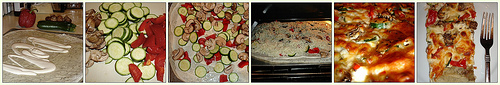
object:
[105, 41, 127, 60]
zuchinni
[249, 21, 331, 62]
pepper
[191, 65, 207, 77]
veggies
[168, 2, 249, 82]
sauce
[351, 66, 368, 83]
cheese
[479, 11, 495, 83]
fork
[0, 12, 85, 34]
table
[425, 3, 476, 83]
dinner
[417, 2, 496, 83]
plate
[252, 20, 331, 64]
pizza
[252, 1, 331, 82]
oven